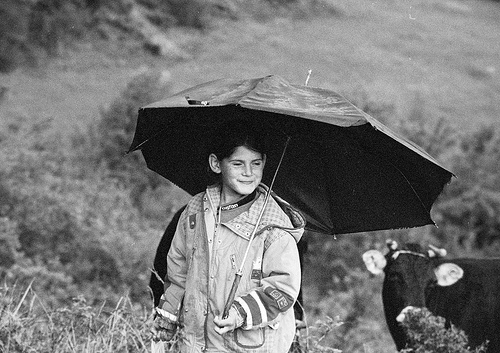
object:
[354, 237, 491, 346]
cow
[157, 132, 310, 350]
girl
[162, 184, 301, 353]
front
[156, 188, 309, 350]
jacket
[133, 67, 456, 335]
umbrella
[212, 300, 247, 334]
hand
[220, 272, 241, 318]
handle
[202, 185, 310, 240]
hood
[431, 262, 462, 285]
ear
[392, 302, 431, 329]
nose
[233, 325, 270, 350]
pocket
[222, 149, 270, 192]
face expression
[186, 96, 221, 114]
hole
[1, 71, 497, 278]
bushes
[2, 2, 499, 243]
background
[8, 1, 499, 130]
grass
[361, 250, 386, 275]
ears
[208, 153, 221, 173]
ear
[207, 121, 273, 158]
hair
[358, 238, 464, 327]
head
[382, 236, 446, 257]
horns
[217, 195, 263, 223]
shirt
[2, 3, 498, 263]
field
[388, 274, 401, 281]
eyes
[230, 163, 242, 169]
eyes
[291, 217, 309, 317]
backpack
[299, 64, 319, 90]
tip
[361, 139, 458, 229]
rib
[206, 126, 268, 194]
head